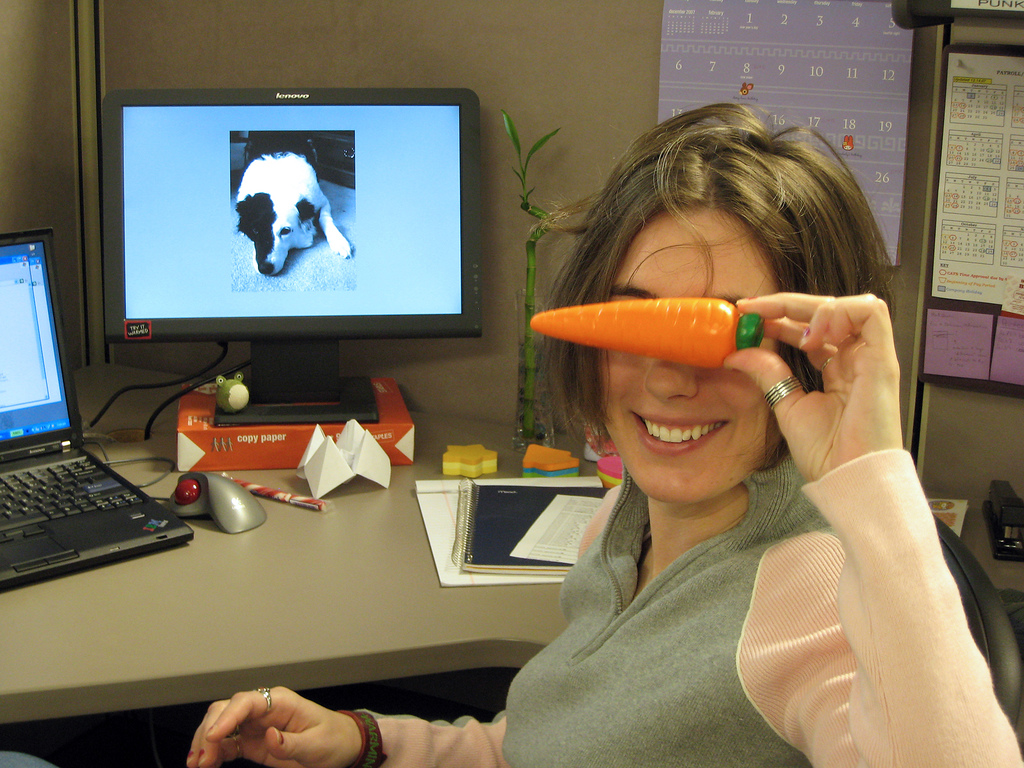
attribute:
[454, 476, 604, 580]
notebook — blue, spiral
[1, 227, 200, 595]
laptop — black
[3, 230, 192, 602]
computer — black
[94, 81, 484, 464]
computer — black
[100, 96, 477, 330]
monitor — black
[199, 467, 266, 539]
computer mouse — black, gray, red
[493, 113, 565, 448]
plant — tall, green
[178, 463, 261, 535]
mouse — gray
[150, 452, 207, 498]
button — red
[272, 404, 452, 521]
paper — white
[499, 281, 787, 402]
carrot — small, fake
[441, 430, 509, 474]
paper pad — colorful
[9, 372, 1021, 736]
desk — tan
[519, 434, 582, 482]
paper pad — colorful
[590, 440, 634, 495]
paper pad — colorful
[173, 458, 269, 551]
computer mouse — grey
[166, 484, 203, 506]
roller ball — red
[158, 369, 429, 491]
package — copy paper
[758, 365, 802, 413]
ring — silver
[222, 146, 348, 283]
dog — white, black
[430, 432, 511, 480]
note pad — yellow, white, star shaped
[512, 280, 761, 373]
carrot — plastic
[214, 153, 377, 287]
dog — white, black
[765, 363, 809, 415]
ring — silver 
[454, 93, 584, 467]
plant — green 